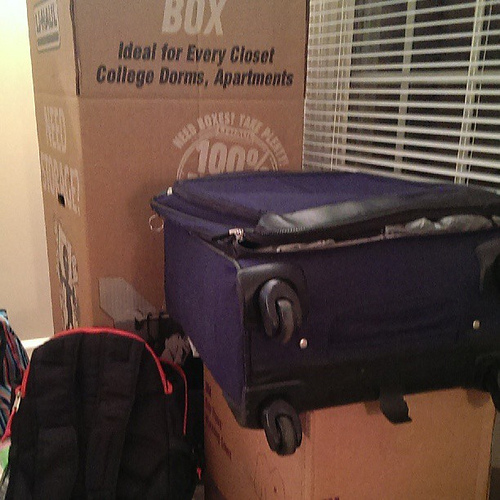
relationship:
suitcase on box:
[136, 126, 472, 422] [24, 8, 306, 179]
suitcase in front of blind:
[136, 126, 472, 422] [297, 12, 487, 137]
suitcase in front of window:
[136, 126, 472, 422] [297, 12, 487, 137]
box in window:
[24, 8, 306, 179] [305, 61, 455, 140]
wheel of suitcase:
[261, 289, 306, 352] [136, 126, 472, 422]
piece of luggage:
[352, 144, 447, 243] [136, 126, 472, 422]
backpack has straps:
[21, 318, 211, 481] [24, 359, 144, 495]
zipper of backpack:
[367, 221, 421, 261] [21, 318, 211, 481]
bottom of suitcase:
[202, 352, 469, 495] [136, 126, 472, 422]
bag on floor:
[21, 318, 211, 481] [94, 457, 232, 491]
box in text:
[24, 8, 306, 179] [163, 27, 253, 82]